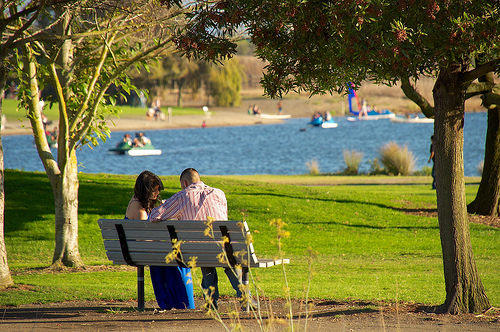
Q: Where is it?
A: This is at the park.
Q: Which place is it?
A: It is a park.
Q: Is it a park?
A: Yes, it is a park.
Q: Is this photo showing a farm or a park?
A: It is showing a park.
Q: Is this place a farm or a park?
A: It is a park.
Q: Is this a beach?
A: No, it is a park.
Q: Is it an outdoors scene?
A: Yes, it is outdoors.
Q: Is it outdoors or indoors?
A: It is outdoors.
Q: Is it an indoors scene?
A: No, it is outdoors.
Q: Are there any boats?
A: Yes, there is a boat.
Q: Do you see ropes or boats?
A: Yes, there is a boat.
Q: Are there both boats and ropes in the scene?
A: No, there is a boat but no ropes.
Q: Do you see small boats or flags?
A: Yes, there is a small boat.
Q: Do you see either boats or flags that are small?
A: Yes, the boat is small.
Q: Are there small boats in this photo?
A: Yes, there is a small boat.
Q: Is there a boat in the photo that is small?
A: Yes, there is a boat that is small.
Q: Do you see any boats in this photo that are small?
A: Yes, there is a boat that is small.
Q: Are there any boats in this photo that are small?
A: Yes, there is a boat that is small.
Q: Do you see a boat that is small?
A: Yes, there is a boat that is small.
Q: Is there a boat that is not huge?
A: Yes, there is a small boat.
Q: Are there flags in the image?
A: No, there are no flags.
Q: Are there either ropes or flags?
A: No, there are no flags or ropes.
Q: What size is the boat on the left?
A: The boat is small.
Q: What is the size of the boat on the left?
A: The boat is small.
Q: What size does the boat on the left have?
A: The boat has small size.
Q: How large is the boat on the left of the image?
A: The boat is small.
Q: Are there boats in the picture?
A: Yes, there is a boat.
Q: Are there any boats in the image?
A: Yes, there is a boat.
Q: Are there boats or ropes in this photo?
A: Yes, there is a boat.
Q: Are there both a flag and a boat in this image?
A: No, there is a boat but no flags.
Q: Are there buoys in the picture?
A: No, there are no buoys.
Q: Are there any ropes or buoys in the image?
A: No, there are no buoys or ropes.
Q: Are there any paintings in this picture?
A: No, there are no paintings.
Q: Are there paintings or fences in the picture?
A: No, there are no paintings or fences.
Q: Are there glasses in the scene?
A: No, there are no glasses.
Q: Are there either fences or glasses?
A: No, there are no glasses or fences.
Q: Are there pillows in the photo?
A: No, there are no pillows.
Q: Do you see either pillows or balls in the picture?
A: No, there are no pillows or balls.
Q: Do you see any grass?
A: Yes, there is grass.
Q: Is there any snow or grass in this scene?
A: Yes, there is grass.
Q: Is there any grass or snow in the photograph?
A: Yes, there is grass.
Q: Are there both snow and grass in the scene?
A: No, there is grass but no snow.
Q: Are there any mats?
A: No, there are no mats.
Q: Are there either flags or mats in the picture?
A: No, there are no mats or flags.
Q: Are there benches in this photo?
A: Yes, there is a bench.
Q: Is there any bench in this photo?
A: Yes, there is a bench.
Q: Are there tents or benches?
A: Yes, there is a bench.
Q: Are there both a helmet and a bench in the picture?
A: No, there is a bench but no helmets.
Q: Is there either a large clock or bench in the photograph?
A: Yes, there is a large bench.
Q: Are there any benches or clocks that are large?
A: Yes, the bench is large.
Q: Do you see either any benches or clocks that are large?
A: Yes, the bench is large.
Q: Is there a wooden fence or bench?
A: Yes, there is a wood bench.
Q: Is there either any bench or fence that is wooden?
A: Yes, the bench is wooden.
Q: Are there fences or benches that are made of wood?
A: Yes, the bench is made of wood.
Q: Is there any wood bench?
A: Yes, there is a bench that is made of wood.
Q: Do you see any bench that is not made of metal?
A: Yes, there is a bench that is made of wood.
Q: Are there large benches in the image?
A: Yes, there is a large bench.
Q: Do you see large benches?
A: Yes, there is a large bench.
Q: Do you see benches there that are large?
A: Yes, there is a bench that is large.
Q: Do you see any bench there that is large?
A: Yes, there is a bench that is large.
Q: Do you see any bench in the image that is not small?
A: Yes, there is a large bench.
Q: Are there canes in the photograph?
A: No, there are no canes.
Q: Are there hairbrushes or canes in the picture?
A: No, there are no canes or hairbrushes.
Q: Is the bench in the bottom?
A: Yes, the bench is in the bottom of the image.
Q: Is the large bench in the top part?
A: No, the bench is in the bottom of the image.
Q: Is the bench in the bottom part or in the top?
A: The bench is in the bottom of the image.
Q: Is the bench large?
A: Yes, the bench is large.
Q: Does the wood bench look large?
A: Yes, the bench is large.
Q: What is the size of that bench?
A: The bench is large.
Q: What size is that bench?
A: The bench is large.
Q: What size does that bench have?
A: The bench has large size.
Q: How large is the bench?
A: The bench is large.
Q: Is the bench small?
A: No, the bench is large.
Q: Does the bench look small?
A: No, the bench is large.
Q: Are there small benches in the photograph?
A: No, there is a bench but it is large.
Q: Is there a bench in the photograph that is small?
A: No, there is a bench but it is large.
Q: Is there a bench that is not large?
A: No, there is a bench but it is large.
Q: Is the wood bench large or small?
A: The bench is large.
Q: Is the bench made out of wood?
A: Yes, the bench is made of wood.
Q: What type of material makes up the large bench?
A: The bench is made of wood.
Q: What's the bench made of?
A: The bench is made of wood.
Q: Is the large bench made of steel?
A: No, the bench is made of wood.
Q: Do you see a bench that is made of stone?
A: No, there is a bench but it is made of wood.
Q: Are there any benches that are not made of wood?
A: No, there is a bench but it is made of wood.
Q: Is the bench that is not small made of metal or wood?
A: The bench is made of wood.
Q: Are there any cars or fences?
A: No, there are no fences or cars.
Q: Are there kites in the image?
A: No, there are no kites.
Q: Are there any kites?
A: No, there are no kites.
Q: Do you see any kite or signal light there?
A: No, there are no kites or traffic lights.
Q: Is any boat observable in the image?
A: Yes, there is a boat.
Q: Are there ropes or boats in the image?
A: Yes, there is a boat.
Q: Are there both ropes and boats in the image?
A: No, there is a boat but no ropes.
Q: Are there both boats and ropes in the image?
A: No, there is a boat but no ropes.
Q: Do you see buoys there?
A: No, there are no buoys.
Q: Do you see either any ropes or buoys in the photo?
A: No, there are no buoys or ropes.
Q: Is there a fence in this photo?
A: No, there are no fences.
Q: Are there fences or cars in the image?
A: No, there are no fences or cars.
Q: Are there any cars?
A: No, there are no cars.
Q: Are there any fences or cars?
A: No, there are no cars or fences.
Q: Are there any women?
A: Yes, there is a woman.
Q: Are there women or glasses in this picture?
A: Yes, there is a woman.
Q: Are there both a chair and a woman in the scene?
A: No, there is a woman but no chairs.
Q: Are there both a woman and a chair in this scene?
A: No, there is a woman but no chairs.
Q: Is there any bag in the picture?
A: No, there are no bags.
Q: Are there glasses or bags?
A: No, there are no bags or glasses.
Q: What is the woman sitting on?
A: The woman is sitting on the bench.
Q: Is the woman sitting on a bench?
A: Yes, the woman is sitting on a bench.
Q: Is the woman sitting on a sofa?
A: No, the woman is sitting on a bench.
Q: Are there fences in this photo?
A: No, there are no fences.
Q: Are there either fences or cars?
A: No, there are no fences or cars.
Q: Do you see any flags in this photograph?
A: No, there are no flags.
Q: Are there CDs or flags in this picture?
A: No, there are no flags or cds.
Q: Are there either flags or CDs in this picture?
A: No, there are no flags or cds.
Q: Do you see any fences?
A: No, there are no fences.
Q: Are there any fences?
A: No, there are no fences.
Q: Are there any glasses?
A: No, there are no glasses.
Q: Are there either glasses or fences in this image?
A: No, there are no glasses or fences.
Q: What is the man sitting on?
A: The man is sitting on the bench.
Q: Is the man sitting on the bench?
A: Yes, the man is sitting on the bench.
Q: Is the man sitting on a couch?
A: No, the man is sitting on the bench.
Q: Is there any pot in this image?
A: No, there are no pots.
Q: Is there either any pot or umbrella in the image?
A: No, there are no pots or umbrellas.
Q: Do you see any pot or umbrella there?
A: No, there are no pots or umbrellas.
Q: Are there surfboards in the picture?
A: No, there are no surfboards.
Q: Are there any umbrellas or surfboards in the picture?
A: No, there are no surfboards or umbrellas.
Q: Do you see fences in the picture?
A: No, there are no fences.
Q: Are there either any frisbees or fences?
A: No, there are no fences or frisbees.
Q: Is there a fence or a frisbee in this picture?
A: No, there are no fences or frisbees.